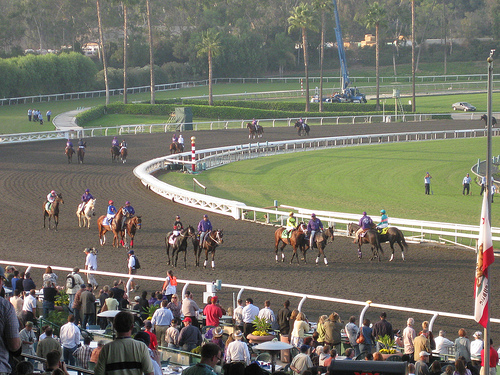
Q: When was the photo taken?
A: During the afternoon.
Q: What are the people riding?
A: Horses.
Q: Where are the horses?
A: On the track.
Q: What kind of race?
A: Horse race.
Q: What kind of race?
A: Horse race.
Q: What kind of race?
A: Horse race.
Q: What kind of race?
A: Horse race.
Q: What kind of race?
A: Horse race.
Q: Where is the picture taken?
A: Racetrack.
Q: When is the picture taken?
A: Daytime.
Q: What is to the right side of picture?
A: A flag.